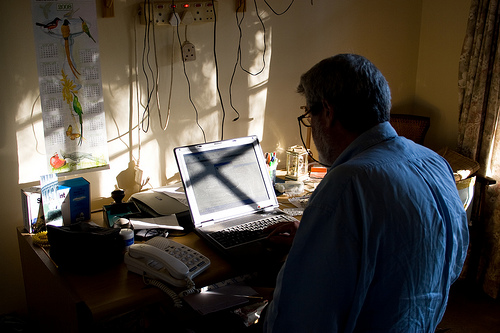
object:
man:
[265, 52, 468, 332]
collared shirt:
[265, 121, 470, 333]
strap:
[298, 120, 331, 168]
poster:
[30, 0, 111, 175]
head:
[296, 52, 391, 168]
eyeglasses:
[298, 109, 312, 127]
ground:
[401, 139, 428, 166]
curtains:
[458, 0, 500, 178]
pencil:
[41, 247, 64, 268]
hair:
[295, 53, 393, 136]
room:
[0, 2, 498, 332]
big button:
[168, 245, 200, 268]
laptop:
[173, 135, 301, 261]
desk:
[11, 168, 498, 316]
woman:
[170, 127, 283, 230]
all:
[9, 41, 49, 164]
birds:
[35, 15, 95, 146]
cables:
[136, 4, 292, 142]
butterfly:
[66, 124, 81, 140]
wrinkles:
[387, 155, 470, 330]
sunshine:
[18, 10, 328, 232]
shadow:
[186, 138, 269, 214]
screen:
[182, 143, 270, 216]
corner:
[20, 228, 90, 315]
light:
[182, 143, 271, 216]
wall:
[2, 3, 475, 322]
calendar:
[32, 1, 110, 174]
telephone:
[125, 236, 211, 307]